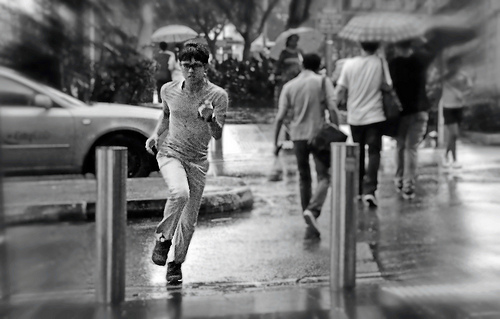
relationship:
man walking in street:
[275, 50, 348, 239] [213, 123, 387, 313]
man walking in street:
[333, 38, 390, 104] [226, 123, 466, 307]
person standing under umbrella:
[274, 31, 314, 98] [267, 16, 327, 67]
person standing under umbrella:
[152, 34, 173, 108] [145, 21, 203, 41]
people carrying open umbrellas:
[143, 43, 464, 191] [145, 2, 477, 60]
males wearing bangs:
[145, 43, 231, 290] [178, 39, 209, 65]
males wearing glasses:
[145, 43, 231, 290] [180, 61, 207, 70]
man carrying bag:
[275, 50, 348, 239] [312, 75, 347, 158]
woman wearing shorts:
[439, 49, 470, 173] [445, 105, 466, 125]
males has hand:
[145, 43, 231, 290] [198, 91, 220, 131]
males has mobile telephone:
[145, 43, 231, 290] [200, 93, 218, 133]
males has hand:
[145, 43, 231, 290] [192, 89, 216, 122]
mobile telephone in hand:
[200, 93, 218, 133] [192, 89, 216, 122]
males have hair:
[145, 39, 427, 303] [173, 22, 383, 83]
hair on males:
[173, 22, 383, 83] [145, 39, 427, 303]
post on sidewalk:
[98, 140, 136, 316] [9, 213, 494, 313]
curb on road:
[16, 166, 253, 219] [13, 123, 495, 290]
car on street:
[0, 57, 179, 179] [0, 114, 498, 310]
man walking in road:
[275, 50, 348, 239] [2, 107, 496, 314]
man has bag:
[278, 50, 348, 239] [315, 67, 351, 147]